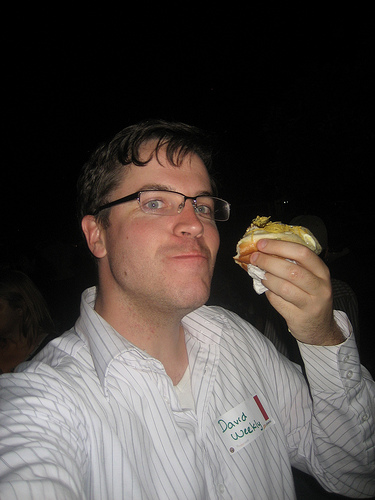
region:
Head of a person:
[65, 112, 232, 332]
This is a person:
[10, 99, 358, 498]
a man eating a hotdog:
[70, 123, 372, 373]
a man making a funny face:
[75, 129, 228, 307]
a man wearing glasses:
[66, 115, 228, 323]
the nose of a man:
[171, 210, 205, 243]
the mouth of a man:
[168, 247, 210, 265]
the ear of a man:
[80, 213, 108, 259]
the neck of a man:
[90, 285, 208, 375]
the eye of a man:
[136, 194, 171, 217]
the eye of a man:
[192, 202, 213, 217]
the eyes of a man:
[136, 195, 216, 218]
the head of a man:
[77, 110, 287, 285]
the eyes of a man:
[117, 181, 257, 236]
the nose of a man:
[147, 205, 239, 257]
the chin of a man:
[158, 266, 227, 327]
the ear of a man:
[61, 206, 117, 287]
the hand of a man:
[230, 223, 338, 340]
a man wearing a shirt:
[13, 97, 288, 480]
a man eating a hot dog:
[124, 130, 352, 328]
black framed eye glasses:
[94, 188, 231, 222]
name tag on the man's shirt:
[213, 395, 275, 456]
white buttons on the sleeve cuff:
[341, 353, 353, 379]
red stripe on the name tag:
[252, 396, 269, 421]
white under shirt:
[170, 365, 194, 412]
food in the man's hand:
[233, 218, 321, 278]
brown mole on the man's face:
[124, 269, 127, 275]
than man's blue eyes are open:
[143, 198, 215, 213]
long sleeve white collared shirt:
[1, 286, 369, 497]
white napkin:
[246, 261, 271, 293]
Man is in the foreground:
[0, 118, 373, 497]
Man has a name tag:
[199, 390, 282, 460]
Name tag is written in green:
[209, 392, 281, 463]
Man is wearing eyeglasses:
[89, 179, 235, 234]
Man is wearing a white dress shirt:
[1, 279, 374, 498]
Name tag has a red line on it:
[211, 382, 283, 465]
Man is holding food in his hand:
[213, 202, 333, 308]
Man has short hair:
[69, 121, 230, 234]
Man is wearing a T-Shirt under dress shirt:
[162, 364, 207, 418]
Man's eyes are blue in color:
[139, 195, 214, 225]